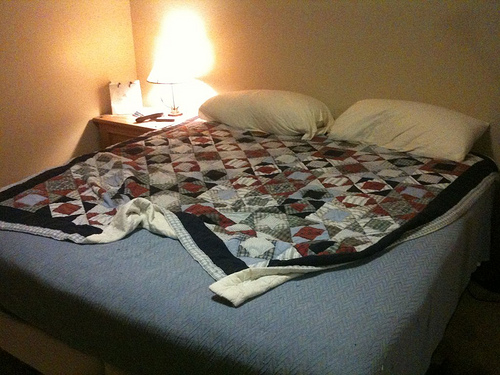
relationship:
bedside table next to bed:
[92, 106, 198, 149] [0, 116, 498, 375]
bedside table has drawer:
[92, 106, 198, 149] [107, 131, 137, 149]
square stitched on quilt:
[235, 137, 257, 144] [0, 115, 499, 308]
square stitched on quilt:
[323, 147, 345, 159] [0, 115, 499, 308]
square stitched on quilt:
[431, 162, 458, 173] [0, 115, 499, 308]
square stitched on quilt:
[203, 168, 226, 181] [0, 115, 499, 308]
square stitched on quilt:
[302, 189, 327, 200] [0, 115, 499, 308]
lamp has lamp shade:
[147, 56, 184, 118] [146, 58, 186, 85]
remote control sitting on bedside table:
[135, 113, 163, 123] [92, 106, 198, 149]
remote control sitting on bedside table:
[155, 117, 176, 123] [92, 106, 198, 149]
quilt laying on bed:
[0, 115, 499, 308] [0, 116, 498, 375]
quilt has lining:
[0, 115, 499, 308] [1, 116, 499, 276]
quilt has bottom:
[0, 115, 499, 308] [88, 198, 307, 310]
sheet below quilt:
[1, 182, 499, 375] [0, 115, 499, 308]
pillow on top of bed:
[199, 89, 333, 142] [0, 116, 498, 375]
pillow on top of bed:
[327, 97, 491, 164] [0, 116, 498, 375]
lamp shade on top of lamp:
[146, 58, 186, 85] [147, 56, 184, 118]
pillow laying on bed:
[199, 89, 333, 142] [0, 116, 498, 375]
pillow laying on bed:
[327, 97, 491, 164] [0, 116, 498, 375]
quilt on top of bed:
[0, 115, 499, 308] [0, 116, 498, 375]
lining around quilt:
[1, 116, 499, 276] [0, 115, 499, 308]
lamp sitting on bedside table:
[147, 56, 184, 118] [92, 106, 198, 149]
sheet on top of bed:
[1, 182, 499, 375] [0, 116, 498, 375]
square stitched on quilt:
[53, 202, 81, 215] [0, 115, 499, 308]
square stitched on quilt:
[292, 223, 325, 241] [0, 115, 499, 308]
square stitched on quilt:
[359, 180, 387, 191] [0, 115, 499, 308]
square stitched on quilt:
[192, 135, 210, 144] [0, 115, 499, 308]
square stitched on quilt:
[16, 193, 48, 206] [0, 115, 499, 308]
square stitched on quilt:
[240, 236, 276, 256] [0, 115, 499, 308]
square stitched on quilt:
[417, 172, 443, 185] [0, 115, 499, 308]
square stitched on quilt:
[377, 168, 403, 179] [0, 115, 499, 308]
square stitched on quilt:
[276, 153, 297, 164] [0, 115, 499, 308]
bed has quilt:
[0, 116, 498, 375] [0, 115, 499, 308]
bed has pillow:
[0, 116, 498, 375] [199, 89, 333, 142]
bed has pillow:
[0, 116, 498, 375] [327, 97, 491, 164]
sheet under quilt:
[1, 182, 499, 375] [0, 115, 499, 308]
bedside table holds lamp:
[92, 106, 198, 149] [147, 56, 184, 118]